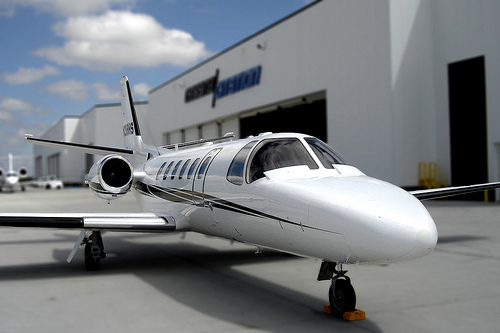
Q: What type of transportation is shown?
A: Plane.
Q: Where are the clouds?
A: In the sky.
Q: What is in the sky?
A: Clouds.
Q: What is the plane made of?
A: Metal.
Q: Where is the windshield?
A: On the front of the plane.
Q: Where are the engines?
A: On the sides of the plane.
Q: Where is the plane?
A: On the tarmac.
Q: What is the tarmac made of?
A: Cement.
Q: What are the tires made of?
A: Rubber.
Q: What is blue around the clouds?
A: The sky.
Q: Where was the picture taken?
A: At an airport.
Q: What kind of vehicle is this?
A: Airplane.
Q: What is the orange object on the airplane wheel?
A: Parking stabilizer for airplane wheel.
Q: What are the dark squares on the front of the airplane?
A: Windshields.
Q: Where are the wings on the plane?
A: On each side of the plane.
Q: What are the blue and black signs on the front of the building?
A: Sign.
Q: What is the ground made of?
A: Paved cement.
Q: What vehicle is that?
A: Airplane.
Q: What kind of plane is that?
A: Private.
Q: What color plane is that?
A: White.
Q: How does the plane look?
A: Small.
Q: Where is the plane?
A: Airport.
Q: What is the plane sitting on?
A: Tarmac.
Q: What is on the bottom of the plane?
A: Wheels.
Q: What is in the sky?
A: Clouds.